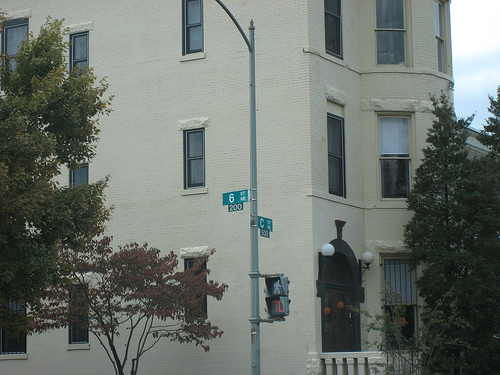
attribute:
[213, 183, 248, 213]
signs — green, white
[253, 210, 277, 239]
signs — green, white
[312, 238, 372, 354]
doorway — black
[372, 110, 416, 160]
blind — white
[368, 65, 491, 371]
tree — leafy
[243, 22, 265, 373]
post — tall ,  metal , street's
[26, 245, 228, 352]
foliage — fall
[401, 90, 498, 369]
leaves — green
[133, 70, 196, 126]
wall — white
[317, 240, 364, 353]
doorway — curved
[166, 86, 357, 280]
wall — cream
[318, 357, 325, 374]
pillar — stone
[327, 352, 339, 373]
pillar — stone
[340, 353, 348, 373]
pillar — stone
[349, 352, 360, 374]
pillar — stone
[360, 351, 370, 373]
pillar — stone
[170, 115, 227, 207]
window — two-part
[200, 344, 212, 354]
bloom — red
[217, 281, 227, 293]
bloom — red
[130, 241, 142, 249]
bloom — red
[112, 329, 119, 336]
bloom — red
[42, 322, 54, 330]
bloom — red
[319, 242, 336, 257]
light globe — white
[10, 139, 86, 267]
tree — evergreen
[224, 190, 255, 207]
lettering — white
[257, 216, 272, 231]
lettering — white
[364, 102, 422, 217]
blind — white